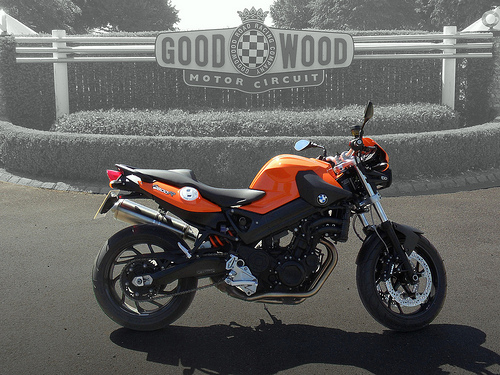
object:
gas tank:
[180, 187, 199, 201]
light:
[106, 169, 122, 182]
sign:
[153, 6, 354, 94]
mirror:
[294, 139, 311, 151]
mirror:
[362, 100, 374, 121]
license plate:
[93, 189, 120, 219]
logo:
[318, 194, 328, 204]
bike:
[91, 100, 448, 331]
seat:
[133, 168, 266, 207]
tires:
[91, 223, 198, 332]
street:
[0, 159, 500, 375]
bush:
[49, 101, 462, 137]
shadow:
[110, 304, 500, 375]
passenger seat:
[133, 168, 199, 189]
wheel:
[356, 225, 447, 332]